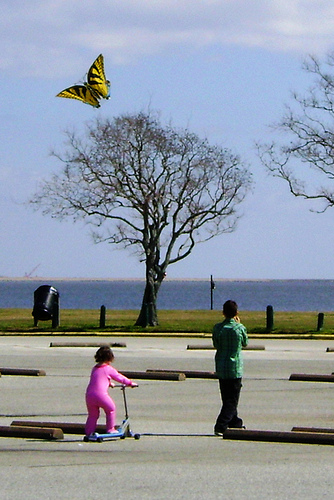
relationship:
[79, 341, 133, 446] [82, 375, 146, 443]
kids on scooter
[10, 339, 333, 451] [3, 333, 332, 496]
bumps on parking lot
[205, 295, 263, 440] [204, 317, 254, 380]
boy wearing shirt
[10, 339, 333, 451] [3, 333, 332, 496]
bumps in parking lot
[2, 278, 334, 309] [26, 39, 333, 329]
water behind trees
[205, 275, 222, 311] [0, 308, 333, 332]
pole in grass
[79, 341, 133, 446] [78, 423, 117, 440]
kids has feet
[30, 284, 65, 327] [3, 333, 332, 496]
can near parking lot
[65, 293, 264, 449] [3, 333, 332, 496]
kids in parking lot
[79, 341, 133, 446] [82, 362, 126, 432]
kids in jumper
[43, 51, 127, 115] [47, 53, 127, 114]
kite shaped like butterfly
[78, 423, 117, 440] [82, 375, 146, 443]
feet on scooter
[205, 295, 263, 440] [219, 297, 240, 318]
boy has hair